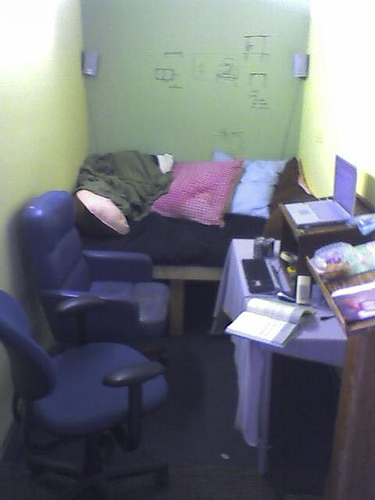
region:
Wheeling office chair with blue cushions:
[0, 287, 167, 495]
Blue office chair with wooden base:
[18, 190, 172, 367]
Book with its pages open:
[222, 295, 314, 348]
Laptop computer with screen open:
[282, 153, 357, 228]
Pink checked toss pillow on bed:
[148, 159, 243, 230]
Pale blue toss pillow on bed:
[213, 152, 285, 220]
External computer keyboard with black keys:
[241, 255, 293, 294]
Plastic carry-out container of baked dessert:
[309, 242, 362, 278]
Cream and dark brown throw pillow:
[70, 189, 128, 237]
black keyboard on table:
[241, 256, 273, 292]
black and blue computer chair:
[0, 286, 171, 498]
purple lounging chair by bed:
[19, 186, 171, 343]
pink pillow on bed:
[150, 153, 244, 224]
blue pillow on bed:
[215, 151, 283, 216]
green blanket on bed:
[80, 147, 166, 222]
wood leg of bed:
[165, 280, 186, 339]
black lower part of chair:
[27, 436, 169, 498]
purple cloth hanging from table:
[217, 239, 343, 451]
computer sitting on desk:
[287, 153, 359, 226]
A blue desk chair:
[25, 189, 168, 340]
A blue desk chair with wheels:
[1, 290, 168, 497]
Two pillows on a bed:
[152, 156, 281, 225]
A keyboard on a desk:
[241, 256, 279, 292]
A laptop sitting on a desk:
[283, 152, 359, 224]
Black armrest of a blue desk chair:
[104, 359, 166, 387]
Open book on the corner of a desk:
[225, 298, 320, 347]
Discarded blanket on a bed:
[82, 149, 172, 219]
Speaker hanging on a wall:
[81, 47, 101, 80]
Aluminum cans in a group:
[253, 233, 275, 260]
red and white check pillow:
[174, 158, 231, 213]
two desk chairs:
[26, 214, 172, 456]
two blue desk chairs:
[20, 197, 164, 442]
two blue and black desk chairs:
[7, 187, 170, 439]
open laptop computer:
[283, 146, 364, 228]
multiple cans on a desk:
[252, 234, 281, 253]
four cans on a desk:
[255, 231, 276, 252]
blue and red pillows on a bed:
[163, 141, 289, 220]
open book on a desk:
[230, 293, 303, 340]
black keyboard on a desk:
[237, 254, 275, 295]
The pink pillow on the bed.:
[154, 152, 238, 224]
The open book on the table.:
[228, 295, 312, 343]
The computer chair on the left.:
[1, 288, 175, 492]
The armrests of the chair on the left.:
[53, 300, 168, 449]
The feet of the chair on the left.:
[30, 450, 171, 498]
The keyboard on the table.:
[241, 253, 287, 300]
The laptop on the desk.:
[276, 157, 361, 230]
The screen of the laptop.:
[333, 160, 354, 214]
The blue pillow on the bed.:
[207, 155, 279, 220]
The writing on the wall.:
[150, 18, 287, 129]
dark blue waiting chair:
[21, 183, 169, 332]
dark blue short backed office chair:
[5, 297, 189, 470]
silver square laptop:
[288, 151, 360, 232]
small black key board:
[237, 236, 273, 302]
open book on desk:
[220, 278, 322, 367]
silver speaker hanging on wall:
[80, 43, 102, 78]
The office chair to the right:
[2, 292, 199, 490]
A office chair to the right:
[0, 290, 193, 482]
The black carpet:
[33, 315, 338, 485]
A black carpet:
[31, 338, 339, 485]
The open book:
[218, 292, 323, 361]